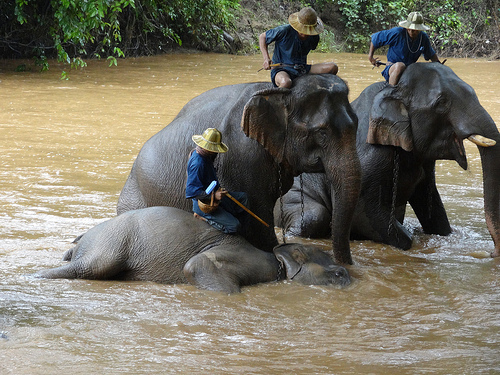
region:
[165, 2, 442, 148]
People wearing hats.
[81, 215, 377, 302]
Elephant laying in the water.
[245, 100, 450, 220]
Chains draping the elephants.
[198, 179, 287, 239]
A person holding a stick.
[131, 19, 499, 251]
Elephants walking through a river.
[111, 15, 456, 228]
People riding elephants.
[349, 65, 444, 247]
An elephant sitting in the water.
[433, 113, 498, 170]
Elephant with tusks attached.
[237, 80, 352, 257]
elephant with chains on its neck.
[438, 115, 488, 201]
Elephant with its mouth open.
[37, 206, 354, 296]
An elephant laying in the water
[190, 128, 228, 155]
A weaved sun hat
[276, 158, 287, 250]
Chains binding the elephants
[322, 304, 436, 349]
Dirty brown turbid water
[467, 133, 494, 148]
A white elephant tusk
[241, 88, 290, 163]
An elephants ear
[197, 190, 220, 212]
A small wooden basket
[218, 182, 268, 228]
A short wooden stick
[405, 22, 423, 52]
A light grey necklace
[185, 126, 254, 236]
A man in a blue outfit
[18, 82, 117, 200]
a river with dirty waters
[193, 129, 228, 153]
a straw hat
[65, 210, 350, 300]
this elephant fell into the water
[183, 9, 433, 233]
three men on the scene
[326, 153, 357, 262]
the long elephant's trunk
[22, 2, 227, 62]
some tree branches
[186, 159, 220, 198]
the long sleeve shirt is blue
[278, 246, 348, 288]
the head of the felt elephant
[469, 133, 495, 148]
the tusk of an elephant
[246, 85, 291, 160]
the big ear of the elephant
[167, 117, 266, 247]
man sitting on an elephant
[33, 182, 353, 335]
elephant laying on his side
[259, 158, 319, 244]
chains around an elephant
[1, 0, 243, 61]
trees that are hanging in the water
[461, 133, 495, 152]
tusks of an elephant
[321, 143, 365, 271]
a large elephant trunk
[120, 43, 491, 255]
elephants sitting in water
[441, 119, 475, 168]
elephant with mouth open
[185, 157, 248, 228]
man wearing blue shirt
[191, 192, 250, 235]
man wearing blue jeans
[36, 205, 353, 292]
Grey elephant lying down in the water.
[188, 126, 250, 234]
A man in a long sleeve blue shirt with a long stick.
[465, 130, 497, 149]
A large fat tan colored tusk.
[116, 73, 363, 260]
The middle grey and brown elephant.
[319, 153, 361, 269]
Long brown and dark grey trunk on an elephant.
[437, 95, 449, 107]
Eye on a elephant with a tusk.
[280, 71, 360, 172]
Head of a dark grey elephant with the biggest dent in his head.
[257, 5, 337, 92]
Man in the darkest blue t-shirt sitting on the middle elephant.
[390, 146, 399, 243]
Metal chain on the elephant with the tusk.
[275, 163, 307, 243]
Two chains on the middle elephant.